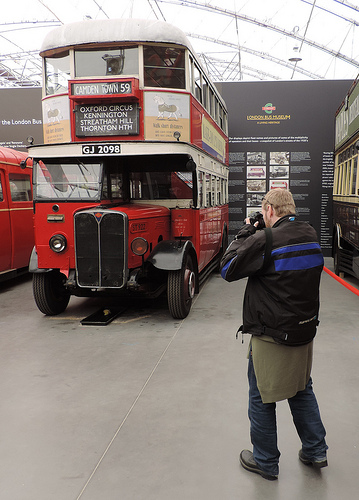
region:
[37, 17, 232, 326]
old fashioned double decker bus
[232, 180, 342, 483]
man taking photograph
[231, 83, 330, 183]
wall of bus museum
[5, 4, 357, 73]
museum glass arched ceiling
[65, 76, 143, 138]
route of the bus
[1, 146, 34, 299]
part of another old-fashioned vehicle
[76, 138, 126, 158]
identification number of bus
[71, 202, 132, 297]
grill of the bus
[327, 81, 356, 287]
small part of another bus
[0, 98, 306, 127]
logos of the bus museum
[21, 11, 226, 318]
one large passenger bus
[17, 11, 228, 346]
one large red passenger bus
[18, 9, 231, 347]
one huge passenger bus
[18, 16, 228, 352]
one huge red passenger bus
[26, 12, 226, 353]
one big passenger bus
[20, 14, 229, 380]
one big red passenger bus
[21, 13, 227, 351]
one tall passenger bus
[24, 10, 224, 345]
one tall red passenger bus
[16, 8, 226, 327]
one double decker passenger bus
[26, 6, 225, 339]
one large double decker passenger bus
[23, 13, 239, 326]
a red and white double-decker bus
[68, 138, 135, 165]
Bus number GJ 2098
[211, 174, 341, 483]
A man in a black and blue coat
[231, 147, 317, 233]
Informative signs on the back wall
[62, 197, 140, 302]
The radiator of a bus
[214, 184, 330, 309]
A man taking a picture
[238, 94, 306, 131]
A sign on the back wall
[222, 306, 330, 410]
A sweater tied around the waist of a man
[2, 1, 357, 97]
A glass ceiling above the bus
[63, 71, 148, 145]
Information where the bus is going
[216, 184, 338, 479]
man taking picture of old bus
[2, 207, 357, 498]
gray stone floor in museum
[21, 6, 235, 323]
red and white double-decker bus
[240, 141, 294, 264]
pictures on black museum wall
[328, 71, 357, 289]
black bus with light yellow windows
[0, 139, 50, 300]
small orange vehicle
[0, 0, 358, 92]
clear glass museum roof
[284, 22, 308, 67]
white light hanging from ceiling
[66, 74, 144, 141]
black sign with white lettering on old bus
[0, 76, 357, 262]
black museum wall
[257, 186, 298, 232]
a head with brown hair.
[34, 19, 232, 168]
the second story on a bus.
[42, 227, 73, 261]
a headlight on a bus.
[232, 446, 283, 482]
the left shoe on a man.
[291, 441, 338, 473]
the right shoe on a man.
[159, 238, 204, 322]
the front left tire on a bus.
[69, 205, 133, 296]
a grill on the front of a bus.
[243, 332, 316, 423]
a sweater around a man's waist.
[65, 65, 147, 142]
a marque above a bus.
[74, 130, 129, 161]
a number on a bus.